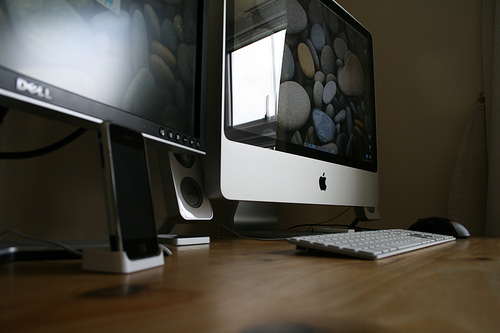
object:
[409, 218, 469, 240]
computer mouse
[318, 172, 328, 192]
apple logo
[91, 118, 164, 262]
phone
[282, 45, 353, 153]
rocks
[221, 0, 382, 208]
apple monitor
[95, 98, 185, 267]
iphone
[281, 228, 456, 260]
computer keyboard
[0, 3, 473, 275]
computer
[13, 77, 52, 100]
lettering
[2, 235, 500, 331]
desk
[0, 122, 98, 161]
cord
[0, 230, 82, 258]
cord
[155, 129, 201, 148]
panel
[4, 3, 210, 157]
monitor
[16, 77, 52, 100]
dell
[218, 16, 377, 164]
picture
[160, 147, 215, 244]
computer speaker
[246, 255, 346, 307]
desk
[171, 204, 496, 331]
desk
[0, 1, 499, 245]
walls